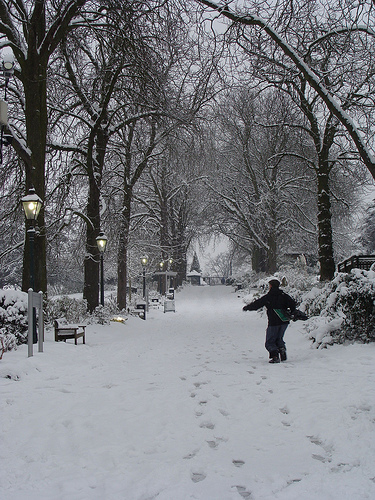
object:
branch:
[124, 47, 201, 104]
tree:
[76, 1, 198, 314]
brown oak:
[85, 96, 101, 307]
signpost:
[27, 292, 44, 359]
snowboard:
[269, 305, 309, 325]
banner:
[25, 286, 45, 359]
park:
[1, 3, 368, 494]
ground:
[4, 283, 374, 499]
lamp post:
[19, 192, 45, 291]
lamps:
[167, 258, 175, 270]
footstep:
[188, 463, 207, 484]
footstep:
[277, 402, 293, 418]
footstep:
[196, 395, 211, 410]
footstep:
[311, 448, 330, 467]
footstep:
[229, 452, 247, 471]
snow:
[1, 283, 372, 498]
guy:
[239, 274, 304, 363]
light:
[27, 200, 40, 213]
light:
[99, 240, 106, 248]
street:
[181, 280, 238, 395]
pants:
[263, 317, 288, 360]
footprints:
[192, 381, 208, 391]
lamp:
[22, 187, 40, 222]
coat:
[244, 286, 299, 329]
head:
[267, 278, 283, 296]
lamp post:
[139, 252, 149, 300]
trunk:
[11, 2, 61, 289]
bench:
[53, 317, 85, 344]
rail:
[336, 252, 373, 269]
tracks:
[167, 325, 364, 498]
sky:
[1, 4, 374, 263]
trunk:
[317, 176, 335, 279]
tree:
[232, 3, 373, 279]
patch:
[88, 337, 246, 474]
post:
[20, 218, 39, 285]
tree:
[142, 29, 198, 292]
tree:
[113, 32, 186, 321]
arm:
[279, 289, 304, 308]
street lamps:
[20, 185, 48, 346]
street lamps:
[89, 228, 111, 304]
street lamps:
[137, 250, 148, 306]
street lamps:
[157, 253, 172, 297]